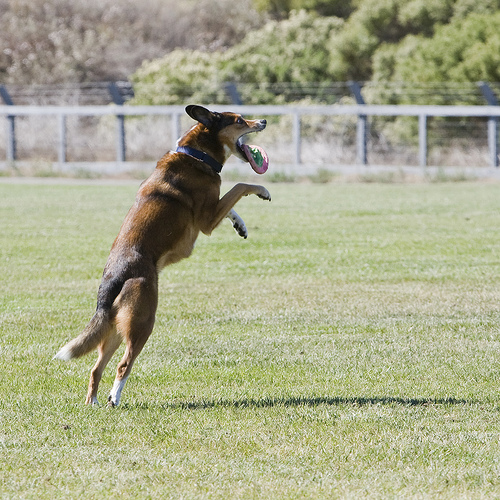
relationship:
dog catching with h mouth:
[57, 102, 272, 406] [238, 125, 273, 173]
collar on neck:
[179, 141, 223, 171] [174, 124, 227, 176]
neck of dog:
[174, 124, 227, 176] [57, 102, 272, 406]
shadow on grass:
[173, 382, 452, 414] [2, 172, 499, 500]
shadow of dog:
[173, 382, 452, 414] [57, 102, 272, 406]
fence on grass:
[1, 80, 498, 169] [2, 172, 499, 500]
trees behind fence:
[136, 11, 500, 156] [1, 80, 498, 169]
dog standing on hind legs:
[57, 102, 272, 406] [89, 283, 159, 408]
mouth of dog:
[238, 125, 273, 173] [57, 102, 272, 406]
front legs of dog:
[205, 179, 274, 239] [57, 102, 272, 406]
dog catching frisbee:
[57, 102, 272, 406] [243, 140, 266, 175]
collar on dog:
[179, 141, 223, 171] [57, 102, 272, 406]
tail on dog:
[57, 290, 111, 368] [57, 102, 272, 406]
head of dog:
[192, 96, 265, 159] [57, 102, 272, 406]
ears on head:
[181, 96, 213, 122] [192, 96, 265, 159]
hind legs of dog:
[89, 283, 159, 408] [57, 102, 272, 406]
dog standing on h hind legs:
[57, 102, 272, 406] [89, 283, 159, 408]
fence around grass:
[1, 80, 498, 169] [2, 172, 499, 500]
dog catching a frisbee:
[57, 102, 272, 406] [243, 140, 266, 175]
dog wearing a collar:
[57, 102, 272, 406] [179, 141, 223, 171]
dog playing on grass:
[57, 102, 272, 406] [2, 172, 499, 500]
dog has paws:
[57, 102, 272, 406] [234, 180, 270, 242]